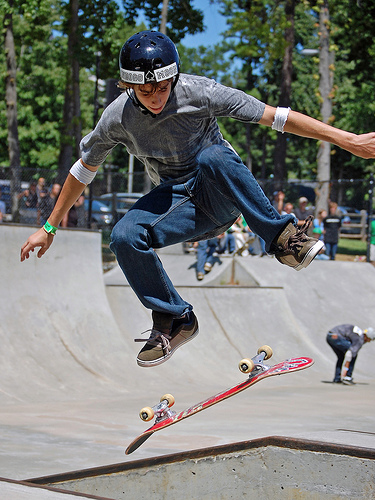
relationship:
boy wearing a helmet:
[16, 30, 373, 366] [112, 28, 181, 86]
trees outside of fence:
[2, 1, 374, 215] [2, 159, 374, 260]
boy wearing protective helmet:
[16, 30, 373, 366] [112, 28, 181, 86]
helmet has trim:
[112, 28, 181, 86] [119, 64, 179, 87]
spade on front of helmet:
[143, 66, 155, 85] [112, 28, 181, 86]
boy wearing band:
[16, 30, 373, 366] [270, 96, 289, 137]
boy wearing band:
[16, 30, 373, 366] [41, 217, 61, 240]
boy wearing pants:
[16, 30, 373, 366] [106, 143, 296, 318]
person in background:
[319, 315, 374, 387] [0, 165, 373, 388]